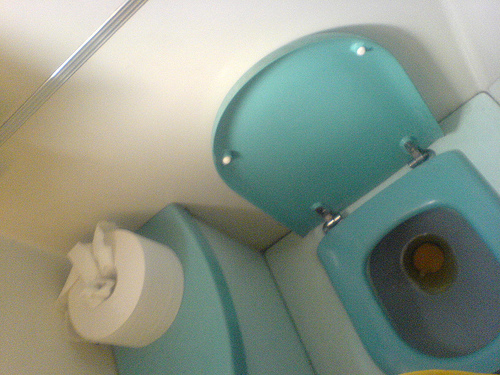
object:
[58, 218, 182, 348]
toilet paper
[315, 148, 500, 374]
seat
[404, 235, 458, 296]
water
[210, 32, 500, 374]
toilet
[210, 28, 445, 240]
lid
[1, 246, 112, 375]
wall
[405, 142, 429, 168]
hinge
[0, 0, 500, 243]
wall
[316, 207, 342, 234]
hinge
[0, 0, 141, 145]
trim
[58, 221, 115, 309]
paper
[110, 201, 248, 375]
ledge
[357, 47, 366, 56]
lid guard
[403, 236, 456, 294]
drain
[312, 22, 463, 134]
shadow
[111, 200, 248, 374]
tank top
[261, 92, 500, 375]
base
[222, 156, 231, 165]
lid guard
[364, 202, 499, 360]
inside